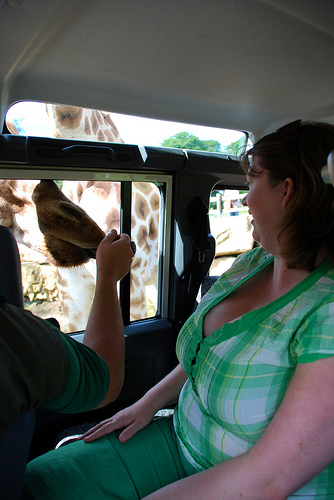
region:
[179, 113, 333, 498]
A woman sitting in a bus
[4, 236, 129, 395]
An arm and hand feeding giraffe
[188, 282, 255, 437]
A green, white and yellow top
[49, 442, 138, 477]
A pair of green pants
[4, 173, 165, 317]
An open car window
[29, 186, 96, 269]
A giraffe eating something from hand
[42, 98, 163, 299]
A tall giraffe watching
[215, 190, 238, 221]
A fence in the background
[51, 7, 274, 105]
The white top of bus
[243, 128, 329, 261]
Woman with dark brown hair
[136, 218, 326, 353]
This is a woman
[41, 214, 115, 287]
This is a mouth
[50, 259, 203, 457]
This is an arm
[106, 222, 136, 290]
This is a hand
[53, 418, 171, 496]
These are green pants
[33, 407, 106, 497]
The pants are green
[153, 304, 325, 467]
The shirt is striped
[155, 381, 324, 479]
The shirt is plaid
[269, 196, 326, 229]
This is an ear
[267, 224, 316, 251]
The hair is short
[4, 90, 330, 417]
passengers in vehicle in zoo park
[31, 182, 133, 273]
hand touching gifaffe's mouth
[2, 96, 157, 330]
giraffes standing outside window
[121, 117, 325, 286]
woman watching from a distance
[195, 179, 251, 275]
person at fencing on top of wall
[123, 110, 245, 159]
tree tops in bright sunlight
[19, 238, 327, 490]
woman in green and white outfit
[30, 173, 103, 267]
front of animal's head shaded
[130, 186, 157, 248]
brown spots with darker markings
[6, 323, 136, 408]
elbow bent below window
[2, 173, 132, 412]
someone is feeding a giraffe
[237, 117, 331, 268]
this woman is smiling and happy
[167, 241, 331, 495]
this woman is wearing a green plaid top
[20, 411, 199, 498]
this woman's green pants match her top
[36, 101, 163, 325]
a second giraffe watches his buddy get a snack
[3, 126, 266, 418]
feeding a giraffe through the window of a vehicle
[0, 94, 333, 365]
this vehicle is probably at a wild animal park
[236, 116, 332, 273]
this woman has brown hair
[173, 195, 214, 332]
no one is wearing this seat belt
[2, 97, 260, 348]
it is a bright sunny day outside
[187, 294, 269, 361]
Cleveage of a woman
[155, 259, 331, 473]
a green an white shirt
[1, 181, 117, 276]
part of a head of a giraffe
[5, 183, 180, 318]
the giraffe is brown and white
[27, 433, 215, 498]
green pants on woman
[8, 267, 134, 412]
an arm in a green sleeve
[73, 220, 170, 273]
a hand touching a giraffe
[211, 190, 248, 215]
a wooden fence seen through window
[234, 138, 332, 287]
brown hair on woamn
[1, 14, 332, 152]
white top of a vehicle